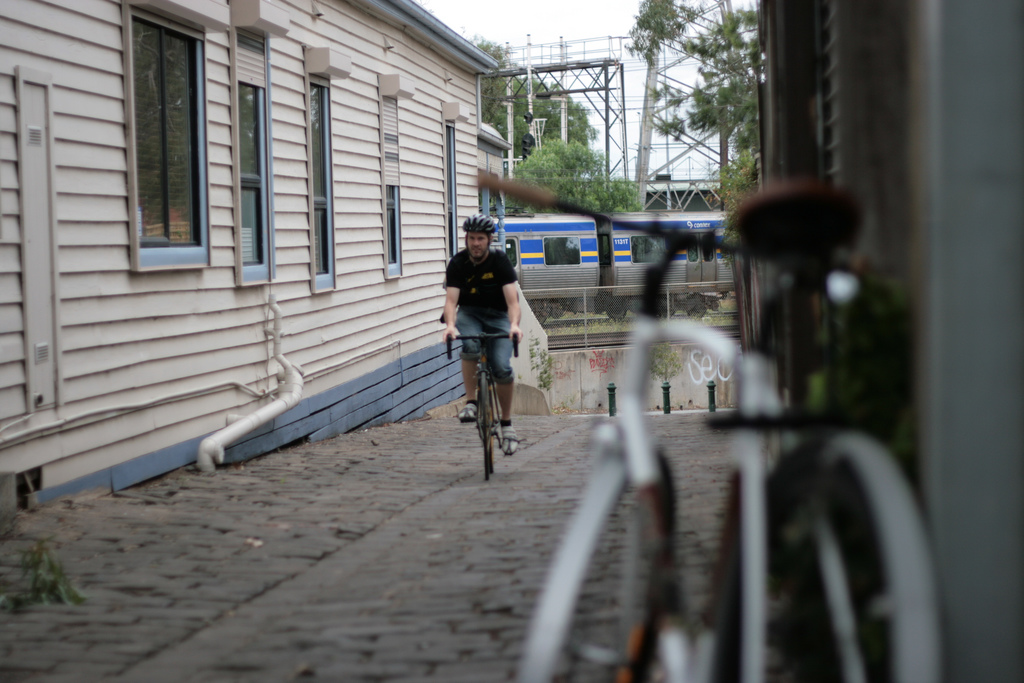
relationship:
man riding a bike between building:
[440, 214, 518, 479] [195, 104, 424, 472]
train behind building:
[492, 212, 749, 302] [102, 244, 170, 526]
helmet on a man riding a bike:
[462, 211, 495, 231] [402, 406, 521, 486]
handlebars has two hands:
[444, 324, 521, 362] [426, 319, 550, 533]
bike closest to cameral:
[472, 160, 941, 670] [594, 265, 731, 499]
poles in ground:
[588, 371, 729, 414] [583, 330, 644, 471]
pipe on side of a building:
[185, 290, 316, 472] [274, 144, 324, 266]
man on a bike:
[440, 214, 518, 479] [332, 81, 684, 506]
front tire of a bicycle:
[430, 369, 528, 516] [446, 330, 517, 477]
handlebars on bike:
[444, 329, 521, 362] [445, 291, 491, 484]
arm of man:
[498, 260, 540, 343] [501, 276, 528, 417]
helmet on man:
[462, 211, 497, 233] [440, 214, 518, 479]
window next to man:
[242, 34, 383, 342] [430, 215, 554, 453]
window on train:
[509, 201, 620, 300] [570, 153, 700, 382]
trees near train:
[478, 68, 616, 223] [478, 212, 739, 299]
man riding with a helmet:
[440, 214, 518, 479] [453, 210, 502, 236]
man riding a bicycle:
[446, 214, 520, 475] [446, 370, 520, 476]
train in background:
[491, 212, 747, 302] [525, 153, 707, 478]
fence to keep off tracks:
[520, 283, 752, 345] [607, 151, 701, 329]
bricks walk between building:
[195, 455, 574, 656] [0, 0, 506, 518]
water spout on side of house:
[203, 345, 283, 574] [89, 261, 306, 609]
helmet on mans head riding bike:
[462, 211, 497, 233] [443, 327, 519, 483]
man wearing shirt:
[440, 214, 518, 479] [446, 247, 520, 321]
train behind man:
[491, 212, 747, 302] [440, 214, 518, 479]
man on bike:
[440, 214, 518, 479] [444, 329, 514, 485]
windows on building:
[127, 14, 460, 297] [0, 0, 506, 518]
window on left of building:
[108, 2, 225, 278] [102, 401, 154, 503]